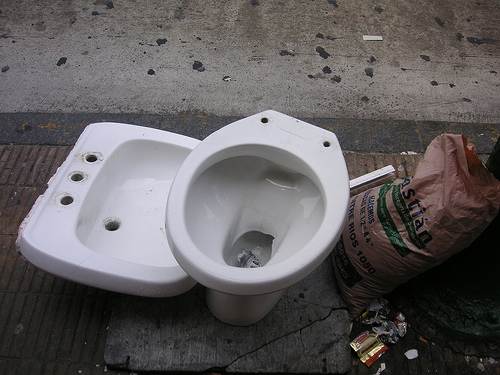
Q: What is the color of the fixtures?
A: White.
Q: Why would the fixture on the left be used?
A: Wash hands.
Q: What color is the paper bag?
A: Brown.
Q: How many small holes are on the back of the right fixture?
A: 2.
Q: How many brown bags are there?
A: 1.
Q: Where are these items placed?
A: Sidewalk.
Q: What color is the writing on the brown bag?
A: Green.